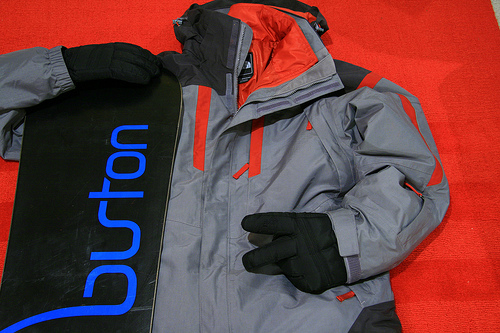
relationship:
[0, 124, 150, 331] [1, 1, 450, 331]
lettering on gray jacket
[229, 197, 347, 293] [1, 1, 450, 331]
glove in gray jacket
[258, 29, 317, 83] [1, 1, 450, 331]
lining in gray jacket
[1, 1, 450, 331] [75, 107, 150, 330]
gray jacket with writing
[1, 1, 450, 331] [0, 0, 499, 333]
gray jacket on carpet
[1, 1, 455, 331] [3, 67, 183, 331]
gray jacket with board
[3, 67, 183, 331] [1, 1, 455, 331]
board on top gray jacket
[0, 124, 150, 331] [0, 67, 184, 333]
lettering on board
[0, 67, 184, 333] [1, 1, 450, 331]
board on gray jacket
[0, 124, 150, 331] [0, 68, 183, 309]
lettering on skateboard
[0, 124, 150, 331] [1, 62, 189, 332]
lettering on snowboard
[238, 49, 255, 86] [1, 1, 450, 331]
tag inside gray jacket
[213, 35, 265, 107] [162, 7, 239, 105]
velcro on jacket neck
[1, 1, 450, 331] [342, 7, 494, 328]
gray jacket on a backing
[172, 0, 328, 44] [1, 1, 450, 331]
hood on gray jacket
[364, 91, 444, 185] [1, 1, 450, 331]
strip on gray jacket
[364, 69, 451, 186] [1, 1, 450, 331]
strip on gray jacket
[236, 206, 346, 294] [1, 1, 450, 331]
glove attached to gray jacket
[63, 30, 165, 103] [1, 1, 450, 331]
glove attached to gray jacket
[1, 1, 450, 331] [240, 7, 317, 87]
gray jacket with lining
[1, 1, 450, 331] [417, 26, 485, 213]
gray jacket on carpet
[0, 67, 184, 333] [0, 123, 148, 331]
board with lettering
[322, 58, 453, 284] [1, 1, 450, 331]
sleeve of gray jacket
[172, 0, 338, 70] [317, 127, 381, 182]
hood is lying on ground